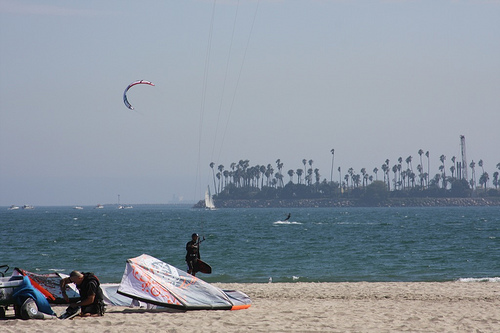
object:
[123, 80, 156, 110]
sail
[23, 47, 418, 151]
clouds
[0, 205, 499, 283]
calm water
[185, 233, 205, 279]
he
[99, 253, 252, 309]
para sail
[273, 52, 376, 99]
blue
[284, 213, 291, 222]
person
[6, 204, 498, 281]
water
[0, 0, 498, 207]
blue sky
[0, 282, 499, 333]
sand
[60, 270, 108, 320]
man